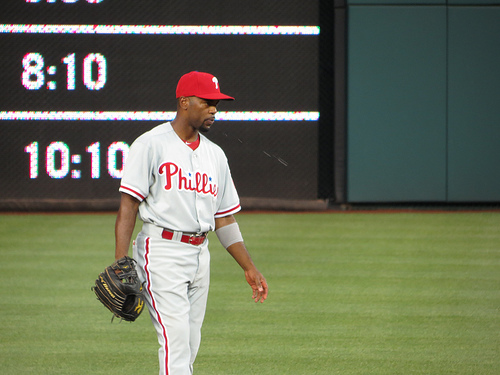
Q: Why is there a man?
A: Playing.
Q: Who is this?
A: Man.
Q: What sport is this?
A: Baseball.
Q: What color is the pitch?
A: Green.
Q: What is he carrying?
A: Gloves.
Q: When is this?
A: Daytime.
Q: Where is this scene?
A: A baseball game.